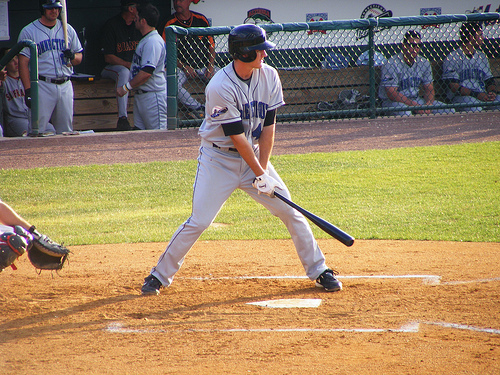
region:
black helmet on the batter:
[225, 23, 275, 64]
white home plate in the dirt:
[243, 294, 325, 310]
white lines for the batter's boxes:
[103, 268, 442, 335]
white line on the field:
[431, 317, 499, 334]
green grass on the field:
[0, 136, 499, 246]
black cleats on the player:
[139, 266, 344, 298]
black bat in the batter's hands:
[249, 175, 356, 248]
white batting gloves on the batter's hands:
[250, 168, 283, 198]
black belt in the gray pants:
[206, 138, 245, 154]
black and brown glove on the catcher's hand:
[22, 229, 72, 274]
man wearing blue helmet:
[234, 26, 249, 36]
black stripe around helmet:
[249, 37, 259, 47]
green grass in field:
[357, 192, 383, 210]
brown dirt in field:
[398, 255, 421, 272]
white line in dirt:
[411, 267, 446, 292]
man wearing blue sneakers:
[312, 265, 349, 297]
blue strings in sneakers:
[321, 268, 336, 280]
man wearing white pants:
[213, 178, 221, 194]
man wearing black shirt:
[228, 124, 240, 134]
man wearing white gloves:
[258, 175, 274, 192]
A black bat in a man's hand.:
[252, 179, 354, 248]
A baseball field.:
[0, 108, 499, 374]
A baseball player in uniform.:
[139, 24, 342, 295]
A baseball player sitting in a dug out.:
[379, 29, 457, 115]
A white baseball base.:
[247, 297, 324, 307]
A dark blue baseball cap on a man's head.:
[227, 23, 277, 55]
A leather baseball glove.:
[27, 231, 69, 271]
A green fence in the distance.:
[165, 11, 499, 131]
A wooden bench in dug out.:
[69, 57, 499, 131]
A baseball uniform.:
[147, 63, 332, 288]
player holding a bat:
[123, 15, 368, 305]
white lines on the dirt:
[101, 255, 495, 355]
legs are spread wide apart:
[133, 176, 353, 298]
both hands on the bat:
[251, 163, 291, 201]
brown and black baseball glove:
[18, 217, 79, 281]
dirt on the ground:
[1, 241, 499, 373]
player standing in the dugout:
[23, 0, 98, 134]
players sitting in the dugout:
[368, 14, 498, 105]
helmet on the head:
[220, 19, 276, 73]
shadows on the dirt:
[1, 268, 330, 358]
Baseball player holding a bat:
[138, 14, 353, 293]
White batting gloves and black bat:
[254, 164, 358, 248]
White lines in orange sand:
[105, 312, 437, 337]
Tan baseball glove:
[16, 225, 71, 275]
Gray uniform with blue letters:
[196, 63, 286, 151]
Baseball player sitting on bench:
[381, 23, 441, 118]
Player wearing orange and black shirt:
[163, 7, 215, 77]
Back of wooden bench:
[290, 70, 372, 109]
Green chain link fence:
[289, 22, 489, 119]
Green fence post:
[164, 27, 181, 127]